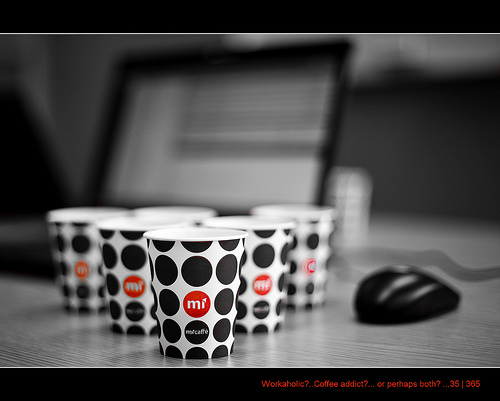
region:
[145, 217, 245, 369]
This is a mug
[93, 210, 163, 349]
This is a mug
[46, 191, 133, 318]
This is a mug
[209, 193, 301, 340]
This is a mug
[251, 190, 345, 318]
This is a mug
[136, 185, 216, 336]
This is a mug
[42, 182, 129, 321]
a mug of yogurt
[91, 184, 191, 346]
a mug of yogurt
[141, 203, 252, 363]
a mug of yogurt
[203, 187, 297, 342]
a mug of yogurt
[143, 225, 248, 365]
a polka dots cup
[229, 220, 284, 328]
a polka dots cup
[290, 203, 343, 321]
a polka dots cup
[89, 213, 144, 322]
a polka dots cup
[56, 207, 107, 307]
a polka dots cup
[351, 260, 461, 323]
the mouse is black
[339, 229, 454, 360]
the mouse is black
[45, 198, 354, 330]
six polka dot drinking cups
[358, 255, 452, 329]
pc mouse to the right of the cups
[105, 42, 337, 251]
blurred pc monitor behind the cups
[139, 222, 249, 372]
clear polka dot in the front of the other cups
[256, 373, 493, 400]
text at the bottom of the photograph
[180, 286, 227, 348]
name of the coffee on the front of the front cup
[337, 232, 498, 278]
a cable behind the PC Mouse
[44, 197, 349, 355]
paper cups lined up in a pyramid pattern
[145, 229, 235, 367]
paper cup in the fron of the other cups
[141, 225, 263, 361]
white cup with black polka dots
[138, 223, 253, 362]
one black, white, and red cup on table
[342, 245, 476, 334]
black computer mouse on table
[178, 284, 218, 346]
one red circle and one black circle on cup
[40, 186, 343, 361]
six cups on table arranged in shape of triangle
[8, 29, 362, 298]
open black laptop on desk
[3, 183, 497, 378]
desk made of wood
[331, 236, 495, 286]
black cord on desk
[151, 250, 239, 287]
three black dots on cup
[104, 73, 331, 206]
white screen of black laptop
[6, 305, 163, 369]
black shadows of cups on wood desk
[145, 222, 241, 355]
cup with white interior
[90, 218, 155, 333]
cup with white interior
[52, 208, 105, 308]
cup with white interior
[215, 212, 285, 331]
cup with white interior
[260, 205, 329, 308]
cup with white interior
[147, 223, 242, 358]
white cup with black dots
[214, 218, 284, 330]
white cup with black dots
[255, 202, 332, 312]
white cup with black dots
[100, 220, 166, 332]
white cup with black dots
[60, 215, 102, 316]
white cup with black dots